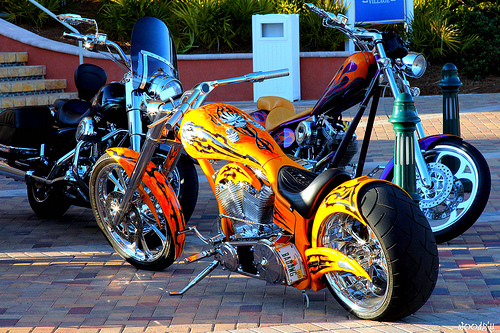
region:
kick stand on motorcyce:
[147, 267, 235, 295]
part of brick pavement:
[37, 276, 104, 331]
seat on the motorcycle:
[285, 167, 337, 184]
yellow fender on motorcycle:
[320, 188, 365, 217]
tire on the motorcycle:
[361, 188, 426, 318]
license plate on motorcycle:
[272, 237, 305, 291]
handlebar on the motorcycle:
[233, 70, 297, 85]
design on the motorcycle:
[214, 107, 269, 151]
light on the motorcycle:
[147, 80, 182, 103]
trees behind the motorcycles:
[181, 2, 236, 36]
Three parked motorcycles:
[11, 6, 491, 318]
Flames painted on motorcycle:
[301, 27, 386, 127]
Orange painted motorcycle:
[59, 58, 471, 310]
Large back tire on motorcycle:
[303, 146, 449, 331]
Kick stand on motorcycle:
[165, 239, 225, 300]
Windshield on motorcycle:
[115, 13, 187, 121]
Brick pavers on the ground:
[6, 216, 475, 331]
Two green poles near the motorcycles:
[363, 47, 485, 199]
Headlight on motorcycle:
[399, 41, 430, 91]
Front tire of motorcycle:
[69, 136, 196, 296]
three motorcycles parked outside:
[1, 0, 493, 322]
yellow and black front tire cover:
[106, 146, 188, 263]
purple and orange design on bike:
[312, 50, 374, 112]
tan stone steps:
[0, 48, 82, 111]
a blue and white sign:
[345, 0, 417, 50]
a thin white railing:
[29, 0, 87, 65]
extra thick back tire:
[322, 178, 440, 321]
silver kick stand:
[163, 258, 220, 297]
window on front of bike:
[128, 13, 182, 86]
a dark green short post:
[437, 62, 464, 135]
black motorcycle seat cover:
[280, 156, 341, 206]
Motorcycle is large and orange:
[117, 55, 444, 318]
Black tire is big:
[322, 182, 442, 314]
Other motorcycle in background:
[306, 26, 453, 131]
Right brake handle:
[56, 7, 103, 45]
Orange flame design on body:
[196, 112, 265, 193]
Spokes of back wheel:
[347, 223, 374, 261]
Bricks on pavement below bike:
[78, 290, 218, 331]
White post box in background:
[251, 10, 303, 100]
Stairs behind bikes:
[3, 42, 65, 107]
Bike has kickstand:
[174, 260, 221, 300]